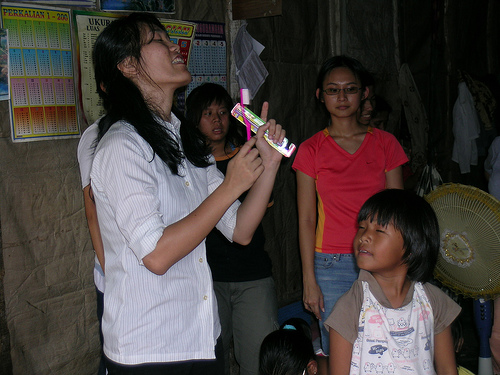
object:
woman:
[290, 56, 410, 355]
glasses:
[321, 86, 363, 94]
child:
[323, 188, 464, 374]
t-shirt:
[323, 269, 464, 373]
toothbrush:
[240, 88, 252, 141]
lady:
[90, 12, 286, 373]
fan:
[414, 182, 500, 372]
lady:
[184, 82, 281, 374]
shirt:
[206, 147, 276, 283]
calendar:
[1, 2, 83, 144]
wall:
[1, 0, 440, 371]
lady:
[255, 317, 320, 375]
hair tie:
[282, 323, 297, 329]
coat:
[398, 60, 433, 171]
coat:
[450, 80, 481, 175]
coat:
[466, 74, 499, 157]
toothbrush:
[231, 102, 297, 158]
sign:
[72, 9, 132, 131]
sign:
[154, 16, 195, 118]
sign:
[184, 20, 226, 102]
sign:
[0, 29, 13, 105]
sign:
[99, 0, 177, 15]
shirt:
[291, 126, 409, 255]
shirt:
[88, 112, 242, 366]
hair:
[88, 13, 214, 176]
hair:
[182, 83, 248, 162]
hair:
[316, 56, 366, 94]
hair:
[355, 188, 440, 287]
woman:
[73, 61, 110, 375]